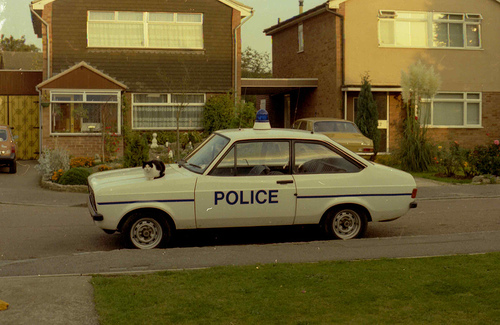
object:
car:
[0, 125, 18, 176]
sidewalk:
[2, 226, 496, 270]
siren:
[250, 107, 274, 127]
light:
[249, 109, 272, 129]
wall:
[390, 94, 448, 155]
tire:
[118, 210, 171, 252]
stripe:
[294, 194, 416, 200]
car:
[266, 118, 374, 163]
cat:
[141, 158, 166, 183]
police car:
[85, 109, 417, 251]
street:
[4, 182, 496, 270]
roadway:
[0, 186, 497, 264]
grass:
[87, 252, 499, 324]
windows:
[207, 138, 291, 178]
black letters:
[210, 187, 279, 206]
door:
[193, 139, 298, 231]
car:
[83, 106, 418, 248]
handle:
[274, 178, 294, 184]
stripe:
[95, 199, 194, 206]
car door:
[190, 135, 298, 230]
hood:
[87, 161, 195, 192]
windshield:
[176, 133, 230, 172]